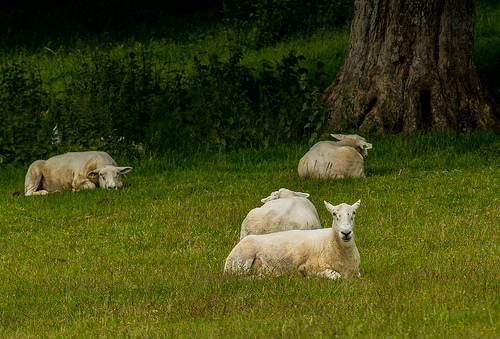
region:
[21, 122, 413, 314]
animal is laying in the grass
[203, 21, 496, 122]
bottom of the tree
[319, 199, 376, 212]
ear of the animal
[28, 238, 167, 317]
a place full of grass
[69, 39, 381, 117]
lot of plants near the tree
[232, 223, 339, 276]
sandle color skin of the animal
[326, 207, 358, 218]
eyes of the animal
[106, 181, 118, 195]
mouth and nose of the animal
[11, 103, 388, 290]
four animals are laying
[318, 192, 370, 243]
animal focusing on the camera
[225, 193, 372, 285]
white sheep lying in field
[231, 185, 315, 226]
white sheep lying in field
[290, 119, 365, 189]
white sheep lying in field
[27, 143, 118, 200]
white sheep lying in field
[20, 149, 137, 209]
white sheep in field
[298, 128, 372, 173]
white sheep in field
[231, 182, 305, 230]
white sheep in field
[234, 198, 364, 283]
white sheep in field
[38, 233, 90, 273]
short green and brown grass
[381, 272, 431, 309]
short green and brown grass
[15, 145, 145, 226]
this is a sheep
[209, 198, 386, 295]
this is a sheep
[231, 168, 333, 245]
this is a sheep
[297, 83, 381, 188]
this is a sheep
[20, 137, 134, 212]
this sheep is white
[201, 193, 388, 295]
this sheep is white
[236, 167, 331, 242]
this sheep is white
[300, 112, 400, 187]
this sheep is white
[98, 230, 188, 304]
this is a patch of grass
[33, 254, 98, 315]
this is a patch of grass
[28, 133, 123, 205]
white sheep on grass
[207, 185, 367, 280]
white sheep on grass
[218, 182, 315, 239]
white sheep on grass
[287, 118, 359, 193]
white sheep on grass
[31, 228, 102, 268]
short yellow and green grass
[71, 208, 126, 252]
short yellow and green grass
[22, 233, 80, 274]
short yellow and green grass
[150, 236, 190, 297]
short yellow and green grass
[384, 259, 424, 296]
short yellow and green grass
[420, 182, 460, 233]
short yellow and green grass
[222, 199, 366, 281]
a white cow in a field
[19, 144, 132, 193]
a white cow in a field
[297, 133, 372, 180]
a white cow in a field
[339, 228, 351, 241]
mouth of a cow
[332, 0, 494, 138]
a thick tree trunk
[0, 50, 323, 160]
shrubs in the distance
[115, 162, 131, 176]
ear of a cow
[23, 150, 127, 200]
a cow laying in grass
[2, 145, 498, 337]
a field of grass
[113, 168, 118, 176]
eye of a cow